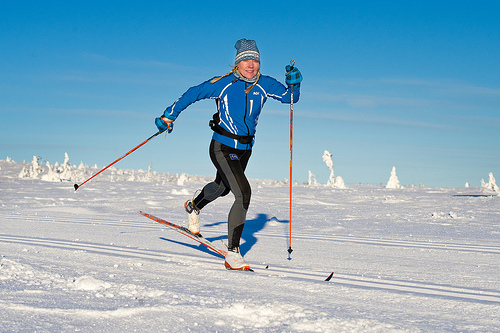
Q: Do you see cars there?
A: No, there are no cars.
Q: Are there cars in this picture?
A: No, there are no cars.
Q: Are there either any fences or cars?
A: No, there are no cars or fences.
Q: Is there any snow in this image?
A: Yes, there is snow.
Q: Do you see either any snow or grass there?
A: Yes, there is snow.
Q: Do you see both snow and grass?
A: No, there is snow but no grass.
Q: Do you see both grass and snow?
A: No, there is snow but no grass.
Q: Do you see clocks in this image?
A: No, there are no clocks.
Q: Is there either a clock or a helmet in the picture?
A: No, there are no clocks or helmets.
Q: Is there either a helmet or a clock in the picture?
A: No, there are no clocks or helmets.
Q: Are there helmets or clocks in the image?
A: No, there are no clocks or helmets.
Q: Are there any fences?
A: No, there are no fences.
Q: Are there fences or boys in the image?
A: No, there are no fences or boys.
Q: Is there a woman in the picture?
A: Yes, there is a woman.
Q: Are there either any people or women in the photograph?
A: Yes, there is a woman.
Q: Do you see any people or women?
A: Yes, there is a woman.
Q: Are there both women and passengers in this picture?
A: No, there is a woman but no passengers.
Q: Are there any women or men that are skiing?
A: Yes, the woman is skiing.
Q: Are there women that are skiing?
A: Yes, there is a woman that is skiing.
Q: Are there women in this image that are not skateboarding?
A: Yes, there is a woman that is skiing.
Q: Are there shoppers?
A: No, there are no shoppers.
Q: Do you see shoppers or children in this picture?
A: No, there are no shoppers or children.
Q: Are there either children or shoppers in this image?
A: No, there are no shoppers or children.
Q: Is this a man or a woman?
A: This is a woman.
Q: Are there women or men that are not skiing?
A: No, there is a woman but she is skiing.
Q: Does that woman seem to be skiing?
A: Yes, the woman is skiing.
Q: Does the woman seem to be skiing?
A: Yes, the woman is skiing.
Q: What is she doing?
A: The woman is skiing.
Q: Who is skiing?
A: The woman is skiing.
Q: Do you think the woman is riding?
A: No, the woman is skiing.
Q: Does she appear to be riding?
A: No, the woman is skiing.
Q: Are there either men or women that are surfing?
A: No, there is a woman but she is skiing.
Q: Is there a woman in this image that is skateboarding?
A: No, there is a woman but she is skiing.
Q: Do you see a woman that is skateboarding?
A: No, there is a woman but she is skiing.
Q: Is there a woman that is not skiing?
A: No, there is a woman but she is skiing.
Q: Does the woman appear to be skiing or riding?
A: The woman is skiing.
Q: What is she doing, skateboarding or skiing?
A: The woman is skiing.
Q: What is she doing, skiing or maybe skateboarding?
A: The woman is skiing.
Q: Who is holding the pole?
A: The woman is holding the pole.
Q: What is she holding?
A: The woman is holding the pole.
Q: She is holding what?
A: The woman is holding the pole.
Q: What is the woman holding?
A: The woman is holding the pole.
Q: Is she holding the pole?
A: Yes, the woman is holding the pole.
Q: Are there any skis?
A: Yes, there are skis.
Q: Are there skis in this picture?
A: Yes, there are skis.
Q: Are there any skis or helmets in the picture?
A: Yes, there are skis.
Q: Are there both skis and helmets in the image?
A: No, there are skis but no helmets.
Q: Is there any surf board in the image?
A: No, there are no surfboards.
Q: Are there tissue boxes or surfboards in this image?
A: No, there are no surfboards or tissue boxes.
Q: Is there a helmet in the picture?
A: No, there are no helmets.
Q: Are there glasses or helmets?
A: No, there are no helmets or glasses.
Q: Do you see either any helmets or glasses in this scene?
A: No, there are no helmets or glasses.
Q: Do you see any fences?
A: No, there are no fences.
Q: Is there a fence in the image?
A: No, there are no fences.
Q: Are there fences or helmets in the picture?
A: No, there are no fences or helmets.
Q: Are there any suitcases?
A: No, there are no suitcases.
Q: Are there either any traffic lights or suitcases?
A: No, there are no suitcases or traffic lights.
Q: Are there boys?
A: No, there are no boys.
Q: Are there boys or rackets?
A: No, there are no boys or rackets.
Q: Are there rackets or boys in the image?
A: No, there are no boys or rackets.